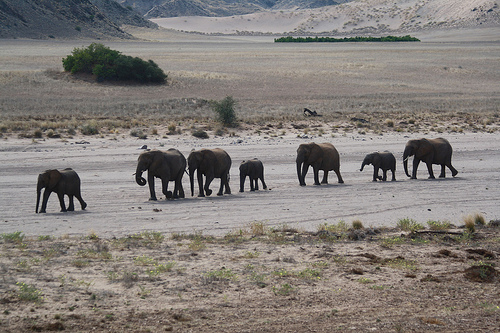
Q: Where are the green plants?
A: On the sand.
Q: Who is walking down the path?
A: A herd of elephants.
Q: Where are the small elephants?
A: In between the big ones.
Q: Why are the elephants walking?
A: Moving in a herd.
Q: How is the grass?
A: Sparse.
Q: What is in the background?
A: Mountains.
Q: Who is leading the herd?
A: Elephant to the far left.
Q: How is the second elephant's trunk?
A: Curled.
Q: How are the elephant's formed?
A: In a line.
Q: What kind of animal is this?
A: Elephant.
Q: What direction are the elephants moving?
A: Left.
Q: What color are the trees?
A: Green.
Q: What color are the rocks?
A: White.